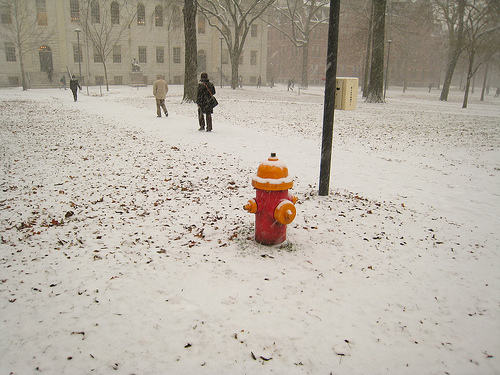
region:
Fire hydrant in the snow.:
[242, 142, 305, 245]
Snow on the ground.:
[43, 282, 380, 369]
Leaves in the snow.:
[28, 132, 195, 259]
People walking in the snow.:
[55, 67, 232, 132]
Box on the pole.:
[328, 69, 361, 114]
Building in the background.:
[8, 1, 272, 98]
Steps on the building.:
[26, 61, 71, 91]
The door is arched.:
[33, 39, 61, 82]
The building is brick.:
[280, 5, 376, 86]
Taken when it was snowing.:
[11, 9, 496, 374]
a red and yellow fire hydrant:
[241, 143, 301, 248]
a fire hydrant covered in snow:
[236, 148, 303, 252]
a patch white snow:
[138, 256, 426, 341]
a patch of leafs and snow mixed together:
[16, 140, 206, 285]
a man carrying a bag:
[187, 70, 226, 130]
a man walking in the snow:
[190, 70, 221, 127]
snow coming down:
[44, 68, 447, 318]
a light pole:
[320, 0, 340, 207]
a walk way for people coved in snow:
[66, 68, 493, 242]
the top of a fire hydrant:
[251, 149, 290, 172]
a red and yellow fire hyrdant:
[245, 152, 300, 246]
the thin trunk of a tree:
[318, 3, 340, 194]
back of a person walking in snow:
[195, 72, 216, 130]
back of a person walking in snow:
[150, 73, 171, 118]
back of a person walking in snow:
[70, 73, 83, 100]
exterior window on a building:
[69, 1, 81, 21]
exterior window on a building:
[2, 40, 14, 61]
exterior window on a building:
[71, 42, 83, 63]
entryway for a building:
[38, 45, 52, 74]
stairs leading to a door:
[25, 68, 70, 88]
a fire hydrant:
[244, 150, 299, 243]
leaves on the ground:
[15, 175, 162, 260]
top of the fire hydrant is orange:
[253, 162, 293, 188]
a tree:
[223, 10, 248, 88]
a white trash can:
[339, 75, 361, 114]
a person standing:
[151, 73, 175, 117]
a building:
[136, 23, 187, 63]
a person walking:
[67, 73, 87, 99]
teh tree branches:
[462, 1, 495, 48]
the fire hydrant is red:
[256, 192, 276, 238]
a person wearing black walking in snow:
[191, 56, 231, 133]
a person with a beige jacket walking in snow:
[145, 61, 170, 123]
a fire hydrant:
[235, 140, 306, 250]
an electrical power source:
[322, 70, 357, 110]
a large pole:
[311, 0, 350, 215]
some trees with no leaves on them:
[420, 15, 491, 120]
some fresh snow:
[142, 281, 401, 362]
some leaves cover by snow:
[36, 203, 95, 235]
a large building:
[23, 3, 94, 73]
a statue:
[123, 52, 145, 90]